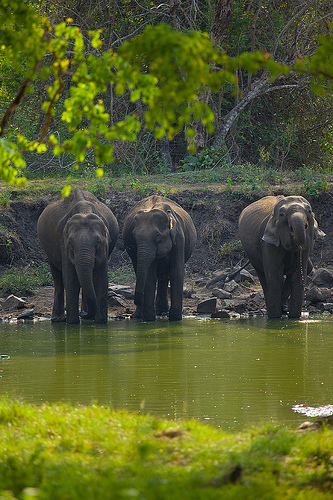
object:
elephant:
[121, 193, 197, 325]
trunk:
[132, 242, 149, 306]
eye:
[153, 231, 164, 243]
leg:
[264, 266, 284, 319]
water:
[0, 315, 331, 431]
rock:
[197, 296, 222, 317]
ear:
[160, 210, 173, 249]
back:
[243, 195, 286, 212]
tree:
[0, 3, 118, 201]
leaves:
[114, 81, 125, 97]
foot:
[48, 311, 66, 328]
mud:
[165, 430, 179, 443]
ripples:
[291, 400, 333, 422]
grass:
[0, 401, 331, 499]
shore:
[1, 259, 332, 324]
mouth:
[288, 245, 304, 254]